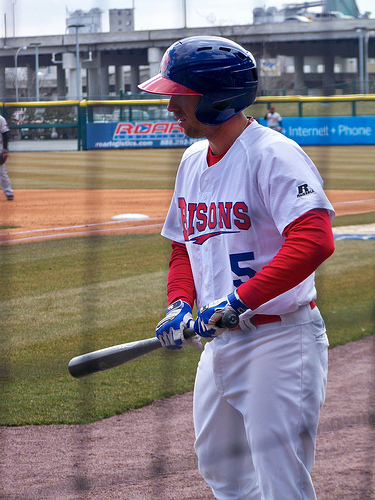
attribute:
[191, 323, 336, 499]
pants — white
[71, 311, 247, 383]
bat — black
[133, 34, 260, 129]
helmet — blue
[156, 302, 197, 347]
glove — blue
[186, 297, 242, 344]
glove — blue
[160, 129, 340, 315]
shirt — white, orange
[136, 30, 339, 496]
person — standing, playing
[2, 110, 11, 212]
person — standing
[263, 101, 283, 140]
person — standing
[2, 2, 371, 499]
baseball — finished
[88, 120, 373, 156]
sign — blue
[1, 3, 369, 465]
outfield — back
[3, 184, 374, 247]
dirt — brown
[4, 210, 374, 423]
grass — green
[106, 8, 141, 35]
building — gray, behind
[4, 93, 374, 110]
fence — yellow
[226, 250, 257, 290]
number — five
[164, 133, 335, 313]
undershirt — red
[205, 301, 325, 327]
belt — red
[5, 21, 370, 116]
deck — behind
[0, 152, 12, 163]
part — glove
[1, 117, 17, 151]
part — elbow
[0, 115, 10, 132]
part —   sleeve